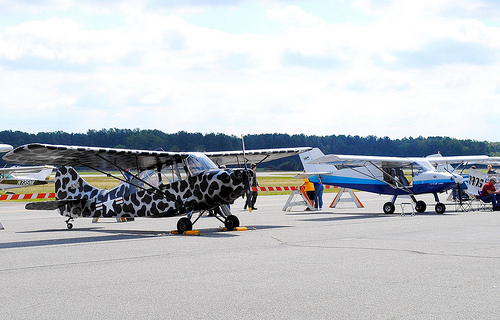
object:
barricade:
[248, 184, 370, 211]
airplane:
[298, 147, 482, 215]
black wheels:
[176, 215, 238, 234]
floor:
[0, 188, 499, 320]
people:
[314, 183, 324, 211]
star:
[102, 193, 115, 214]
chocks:
[168, 230, 200, 236]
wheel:
[177, 217, 192, 234]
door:
[383, 166, 414, 186]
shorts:
[306, 191, 318, 200]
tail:
[291, 147, 338, 179]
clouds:
[0, 4, 500, 142]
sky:
[0, 0, 500, 142]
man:
[478, 175, 500, 210]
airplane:
[2, 142, 314, 235]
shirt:
[303, 178, 315, 192]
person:
[300, 177, 316, 211]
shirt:
[481, 182, 498, 197]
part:
[239, 273, 355, 320]